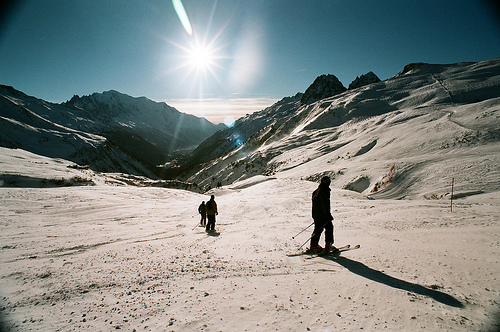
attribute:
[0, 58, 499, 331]
mountains — snowy, snow covered, rocky, rough, majestic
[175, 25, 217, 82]
sun — bright, shining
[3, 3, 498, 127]
sky — clear, bright, blue, beautiful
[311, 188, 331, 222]
jacket — black, dark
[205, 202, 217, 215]
jacket — yellow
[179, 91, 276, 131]
clouds — white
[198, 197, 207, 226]
person — skiing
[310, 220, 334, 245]
pants — black